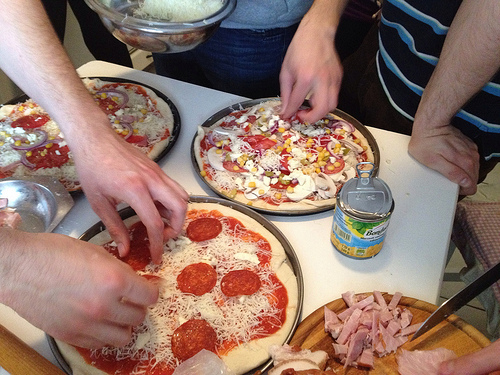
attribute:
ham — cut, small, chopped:
[343, 332, 368, 373]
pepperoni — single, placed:
[175, 263, 218, 298]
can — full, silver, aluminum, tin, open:
[332, 180, 395, 261]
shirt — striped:
[376, 1, 499, 164]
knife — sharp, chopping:
[408, 263, 498, 347]